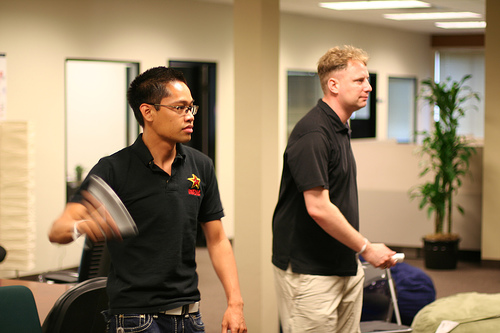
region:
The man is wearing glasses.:
[131, 70, 204, 145]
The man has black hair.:
[124, 68, 199, 137]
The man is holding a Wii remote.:
[55, 165, 133, 245]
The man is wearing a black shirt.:
[145, 184, 185, 221]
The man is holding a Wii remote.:
[337, 230, 414, 276]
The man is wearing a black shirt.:
[316, 140, 346, 163]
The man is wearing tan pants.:
[302, 282, 334, 315]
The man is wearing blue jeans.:
[115, 316, 196, 331]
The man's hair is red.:
[315, 48, 385, 120]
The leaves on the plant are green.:
[423, 78, 466, 180]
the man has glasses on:
[65, 70, 256, 331]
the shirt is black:
[267, 90, 383, 275]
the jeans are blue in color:
[119, 310, 205, 331]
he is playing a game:
[53, 69, 253, 331]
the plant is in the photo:
[416, 94, 480, 226]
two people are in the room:
[1, 9, 496, 331]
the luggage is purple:
[394, 261, 439, 311]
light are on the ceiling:
[376, 10, 481, 42]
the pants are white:
[268, 264, 372, 331]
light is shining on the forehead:
[166, 79, 201, 100]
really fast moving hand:
[60, 175, 142, 262]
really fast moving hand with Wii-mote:
[69, 170, 154, 262]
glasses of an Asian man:
[146, 101, 216, 118]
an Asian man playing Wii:
[46, 48, 292, 326]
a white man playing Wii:
[270, 43, 413, 331]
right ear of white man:
[327, 70, 347, 99]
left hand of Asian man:
[207, 296, 255, 331]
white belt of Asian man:
[166, 300, 210, 317]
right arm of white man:
[295, 134, 405, 271]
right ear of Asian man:
[131, 102, 153, 123]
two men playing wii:
[66, 33, 406, 328]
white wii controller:
[362, 245, 412, 272]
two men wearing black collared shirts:
[85, 113, 370, 296]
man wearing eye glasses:
[131, 62, 207, 145]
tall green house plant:
[415, 59, 482, 266]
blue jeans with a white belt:
[105, 298, 210, 330]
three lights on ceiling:
[303, 0, 485, 30]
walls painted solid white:
[37, 17, 64, 187]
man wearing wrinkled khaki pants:
[267, 250, 375, 328]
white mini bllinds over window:
[420, 40, 490, 147]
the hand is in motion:
[16, 170, 155, 239]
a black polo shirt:
[136, 176, 213, 272]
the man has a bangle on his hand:
[331, 213, 379, 271]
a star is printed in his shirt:
[181, 172, 211, 194]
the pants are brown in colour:
[276, 277, 359, 328]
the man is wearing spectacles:
[128, 65, 196, 142]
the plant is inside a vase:
[418, 79, 470, 274]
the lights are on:
[336, 0, 481, 32]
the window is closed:
[435, 60, 483, 143]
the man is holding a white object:
[44, 96, 237, 331]